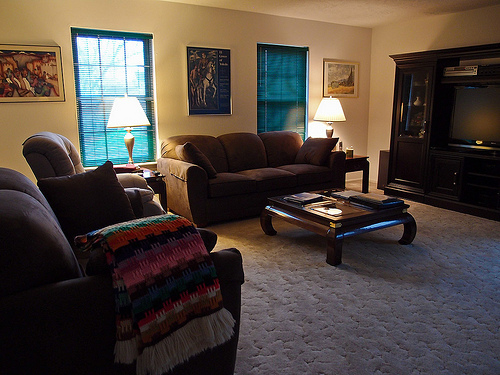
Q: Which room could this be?
A: It is a living room.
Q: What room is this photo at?
A: It is at the living room.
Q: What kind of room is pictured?
A: It is a living room.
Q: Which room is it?
A: It is a living room.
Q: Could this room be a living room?
A: Yes, it is a living room.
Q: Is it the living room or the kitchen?
A: It is the living room.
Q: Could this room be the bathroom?
A: No, it is the living room.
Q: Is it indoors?
A: Yes, it is indoors.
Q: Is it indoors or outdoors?
A: It is indoors.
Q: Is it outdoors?
A: No, it is indoors.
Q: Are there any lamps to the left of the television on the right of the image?
A: Yes, there are lamps to the left of the TV.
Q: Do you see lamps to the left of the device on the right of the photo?
A: Yes, there are lamps to the left of the TV.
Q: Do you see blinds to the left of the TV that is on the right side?
A: No, there are lamps to the left of the TV.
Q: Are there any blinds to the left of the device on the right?
A: No, there are lamps to the left of the TV.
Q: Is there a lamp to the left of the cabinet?
A: Yes, there are lamps to the left of the cabinet.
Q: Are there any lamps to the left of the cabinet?
A: Yes, there are lamps to the left of the cabinet.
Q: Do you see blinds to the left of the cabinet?
A: No, there are lamps to the left of the cabinet.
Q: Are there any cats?
A: No, there are no cats.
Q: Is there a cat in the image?
A: No, there are no cats.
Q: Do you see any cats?
A: No, there are no cats.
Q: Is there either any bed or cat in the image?
A: No, there are no cats or beds.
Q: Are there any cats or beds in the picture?
A: No, there are no cats or beds.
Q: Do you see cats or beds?
A: No, there are no cats or beds.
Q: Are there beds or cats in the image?
A: No, there are no cats or beds.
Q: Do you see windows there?
A: Yes, there is a window.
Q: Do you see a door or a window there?
A: Yes, there is a window.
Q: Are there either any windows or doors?
A: Yes, there is a window.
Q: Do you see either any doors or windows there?
A: Yes, there is a window.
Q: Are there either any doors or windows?
A: Yes, there is a window.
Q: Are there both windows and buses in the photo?
A: No, there is a window but no buses.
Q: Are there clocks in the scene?
A: No, there are no clocks.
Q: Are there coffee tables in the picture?
A: Yes, there is a coffee table.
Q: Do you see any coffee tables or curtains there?
A: Yes, there is a coffee table.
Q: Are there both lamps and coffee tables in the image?
A: Yes, there are both a coffee table and a lamp.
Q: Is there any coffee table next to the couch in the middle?
A: Yes, there is a coffee table next to the couch.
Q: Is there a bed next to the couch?
A: No, there is a coffee table next to the couch.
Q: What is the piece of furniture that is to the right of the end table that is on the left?
A: The piece of furniture is a coffee table.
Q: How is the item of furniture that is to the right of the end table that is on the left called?
A: The piece of furniture is a coffee table.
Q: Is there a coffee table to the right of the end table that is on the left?
A: Yes, there is a coffee table to the right of the end table.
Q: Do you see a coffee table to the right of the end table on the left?
A: Yes, there is a coffee table to the right of the end table.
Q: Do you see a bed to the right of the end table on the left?
A: No, there is a coffee table to the right of the end table.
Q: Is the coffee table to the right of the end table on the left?
A: Yes, the coffee table is to the right of the end table.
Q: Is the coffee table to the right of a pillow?
A: No, the coffee table is to the right of the end table.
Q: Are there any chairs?
A: Yes, there is a chair.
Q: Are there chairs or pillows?
A: Yes, there is a chair.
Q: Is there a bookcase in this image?
A: No, there are no bookcases.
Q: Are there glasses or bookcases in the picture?
A: No, there are no bookcases or glasses.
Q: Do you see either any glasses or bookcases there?
A: No, there are no bookcases or glasses.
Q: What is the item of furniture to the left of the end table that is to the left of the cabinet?
A: The piece of furniture is a chair.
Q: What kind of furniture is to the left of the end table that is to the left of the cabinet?
A: The piece of furniture is a chair.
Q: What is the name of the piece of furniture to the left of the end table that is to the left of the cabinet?
A: The piece of furniture is a chair.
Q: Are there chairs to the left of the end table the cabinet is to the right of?
A: Yes, there is a chair to the left of the end table.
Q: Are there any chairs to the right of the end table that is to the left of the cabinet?
A: No, the chair is to the left of the end table.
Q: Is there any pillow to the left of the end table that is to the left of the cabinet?
A: No, there is a chair to the left of the end table.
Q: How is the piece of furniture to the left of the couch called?
A: The piece of furniture is a chair.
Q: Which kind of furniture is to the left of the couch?
A: The piece of furniture is a chair.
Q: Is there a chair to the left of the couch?
A: Yes, there is a chair to the left of the couch.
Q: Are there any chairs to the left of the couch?
A: Yes, there is a chair to the left of the couch.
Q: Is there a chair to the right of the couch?
A: No, the chair is to the left of the couch.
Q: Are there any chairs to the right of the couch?
A: No, the chair is to the left of the couch.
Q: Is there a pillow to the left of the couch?
A: No, there is a chair to the left of the couch.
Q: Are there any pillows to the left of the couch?
A: No, there is a chair to the left of the couch.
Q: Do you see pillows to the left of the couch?
A: No, there is a chair to the left of the couch.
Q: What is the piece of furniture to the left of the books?
A: The piece of furniture is a chair.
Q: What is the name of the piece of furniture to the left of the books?
A: The piece of furniture is a chair.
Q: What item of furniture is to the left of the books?
A: The piece of furniture is a chair.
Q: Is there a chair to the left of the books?
A: Yes, there is a chair to the left of the books.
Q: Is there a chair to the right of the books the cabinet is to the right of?
A: No, the chair is to the left of the books.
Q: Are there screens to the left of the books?
A: No, there is a chair to the left of the books.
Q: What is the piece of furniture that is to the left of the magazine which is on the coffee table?
A: The piece of furniture is a chair.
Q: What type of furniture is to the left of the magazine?
A: The piece of furniture is a chair.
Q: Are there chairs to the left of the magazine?
A: Yes, there is a chair to the left of the magazine.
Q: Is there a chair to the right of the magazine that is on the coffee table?
A: No, the chair is to the left of the magazine.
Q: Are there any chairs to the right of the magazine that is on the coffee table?
A: No, the chair is to the left of the magazine.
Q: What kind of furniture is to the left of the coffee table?
A: The piece of furniture is a chair.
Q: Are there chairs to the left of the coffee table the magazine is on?
A: Yes, there is a chair to the left of the coffee table.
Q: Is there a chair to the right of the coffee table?
A: No, the chair is to the left of the coffee table.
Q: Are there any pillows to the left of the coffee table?
A: No, there is a chair to the left of the coffee table.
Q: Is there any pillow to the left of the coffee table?
A: No, there is a chair to the left of the coffee table.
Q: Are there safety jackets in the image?
A: No, there are no safety jackets.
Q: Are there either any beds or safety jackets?
A: No, there are no safety jackets or beds.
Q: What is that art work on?
A: The art work is on the wall.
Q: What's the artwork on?
A: The art work is on the wall.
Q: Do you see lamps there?
A: Yes, there is a lamp.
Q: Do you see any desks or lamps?
A: Yes, there is a lamp.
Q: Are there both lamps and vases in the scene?
A: No, there is a lamp but no vases.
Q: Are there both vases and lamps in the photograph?
A: No, there is a lamp but no vases.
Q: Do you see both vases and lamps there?
A: No, there is a lamp but no vases.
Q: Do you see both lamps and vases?
A: No, there is a lamp but no vases.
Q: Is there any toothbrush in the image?
A: No, there are no toothbrushes.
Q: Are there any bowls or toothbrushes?
A: No, there are no toothbrushes or bowls.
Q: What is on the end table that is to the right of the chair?
A: The lamp is on the end table.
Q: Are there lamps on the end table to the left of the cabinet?
A: Yes, there is a lamp on the end table.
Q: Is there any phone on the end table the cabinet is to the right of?
A: No, there is a lamp on the end table.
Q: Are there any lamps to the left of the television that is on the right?
A: Yes, there is a lamp to the left of the TV.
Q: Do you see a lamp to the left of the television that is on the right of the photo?
A: Yes, there is a lamp to the left of the TV.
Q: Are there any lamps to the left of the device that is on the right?
A: Yes, there is a lamp to the left of the TV.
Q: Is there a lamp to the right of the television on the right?
A: No, the lamp is to the left of the TV.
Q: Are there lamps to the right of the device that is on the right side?
A: No, the lamp is to the left of the TV.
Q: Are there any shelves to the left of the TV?
A: No, there is a lamp to the left of the TV.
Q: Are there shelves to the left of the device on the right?
A: No, there is a lamp to the left of the TV.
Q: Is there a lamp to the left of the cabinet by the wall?
A: Yes, there is a lamp to the left of the cabinet.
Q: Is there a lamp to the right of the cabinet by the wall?
A: No, the lamp is to the left of the cabinet.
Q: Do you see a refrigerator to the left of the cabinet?
A: No, there is a lamp to the left of the cabinet.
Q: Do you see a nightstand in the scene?
A: No, there are no nightstands.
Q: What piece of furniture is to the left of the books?
A: The piece of furniture is an end table.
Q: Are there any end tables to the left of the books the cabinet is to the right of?
A: Yes, there is an end table to the left of the books.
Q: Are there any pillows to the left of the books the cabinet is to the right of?
A: No, there is an end table to the left of the books.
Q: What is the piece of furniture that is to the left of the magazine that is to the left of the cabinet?
A: The piece of furniture is an end table.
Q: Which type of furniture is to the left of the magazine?
A: The piece of furniture is an end table.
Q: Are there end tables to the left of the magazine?
A: Yes, there is an end table to the left of the magazine.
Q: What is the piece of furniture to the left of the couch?
A: The piece of furniture is an end table.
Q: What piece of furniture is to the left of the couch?
A: The piece of furniture is an end table.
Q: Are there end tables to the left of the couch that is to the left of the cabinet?
A: Yes, there is an end table to the left of the couch.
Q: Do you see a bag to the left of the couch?
A: No, there is an end table to the left of the couch.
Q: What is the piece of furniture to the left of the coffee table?
A: The piece of furniture is an end table.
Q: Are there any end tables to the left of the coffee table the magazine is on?
A: Yes, there is an end table to the left of the coffee table.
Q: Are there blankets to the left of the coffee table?
A: No, there is an end table to the left of the coffee table.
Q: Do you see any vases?
A: No, there are no vases.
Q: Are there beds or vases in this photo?
A: No, there are no vases or beds.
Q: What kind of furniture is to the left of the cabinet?
A: The piece of furniture is an end table.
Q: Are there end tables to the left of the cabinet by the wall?
A: Yes, there is an end table to the left of the cabinet.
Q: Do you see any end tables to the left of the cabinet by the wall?
A: Yes, there is an end table to the left of the cabinet.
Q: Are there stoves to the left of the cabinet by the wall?
A: No, there is an end table to the left of the cabinet.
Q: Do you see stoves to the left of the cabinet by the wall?
A: No, there is an end table to the left of the cabinet.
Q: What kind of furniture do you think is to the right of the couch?
A: The piece of furniture is an end table.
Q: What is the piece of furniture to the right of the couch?
A: The piece of furniture is an end table.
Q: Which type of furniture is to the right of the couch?
A: The piece of furniture is an end table.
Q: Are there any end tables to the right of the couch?
A: Yes, there is an end table to the right of the couch.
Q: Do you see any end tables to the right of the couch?
A: Yes, there is an end table to the right of the couch.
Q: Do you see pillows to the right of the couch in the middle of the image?
A: No, there is an end table to the right of the couch.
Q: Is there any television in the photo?
A: Yes, there is a television.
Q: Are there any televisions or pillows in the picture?
A: Yes, there is a television.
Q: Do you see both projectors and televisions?
A: No, there is a television but no projectors.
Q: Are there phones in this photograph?
A: No, there are no phones.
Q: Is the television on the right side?
A: Yes, the television is on the right of the image.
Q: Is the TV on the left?
A: No, the TV is on the right of the image.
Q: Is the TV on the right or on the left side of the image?
A: The TV is on the right of the image.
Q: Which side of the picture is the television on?
A: The television is on the right of the image.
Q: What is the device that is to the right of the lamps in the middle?
A: The device is a television.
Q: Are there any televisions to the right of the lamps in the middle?
A: Yes, there is a television to the right of the lamps.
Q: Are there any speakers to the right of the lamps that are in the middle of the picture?
A: No, there is a television to the right of the lamps.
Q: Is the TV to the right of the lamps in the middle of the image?
A: Yes, the TV is to the right of the lamps.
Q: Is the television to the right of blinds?
A: No, the television is to the right of the lamps.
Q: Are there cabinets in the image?
A: Yes, there is a cabinet.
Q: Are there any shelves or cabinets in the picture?
A: Yes, there is a cabinet.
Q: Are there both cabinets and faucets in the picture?
A: No, there is a cabinet but no faucets.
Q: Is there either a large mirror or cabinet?
A: Yes, there is a large cabinet.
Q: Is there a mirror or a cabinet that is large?
A: Yes, the cabinet is large.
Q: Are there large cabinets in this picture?
A: Yes, there is a large cabinet.